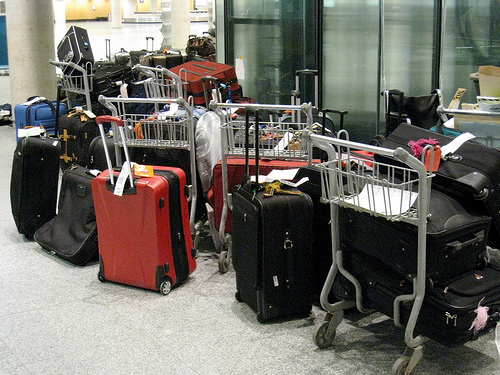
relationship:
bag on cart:
[327, 174, 488, 285] [306, 130, 438, 373]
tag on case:
[133, 162, 156, 177] [89, 162, 198, 293]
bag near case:
[327, 174, 488, 285] [89, 162, 198, 293]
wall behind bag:
[215, 0, 499, 110] [327, 174, 488, 285]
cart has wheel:
[306, 130, 438, 373] [313, 321, 336, 351]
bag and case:
[327, 174, 488, 285] [89, 162, 198, 293]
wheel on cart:
[313, 321, 336, 351] [306, 130, 438, 373]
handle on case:
[95, 114, 136, 187] [89, 162, 198, 293]